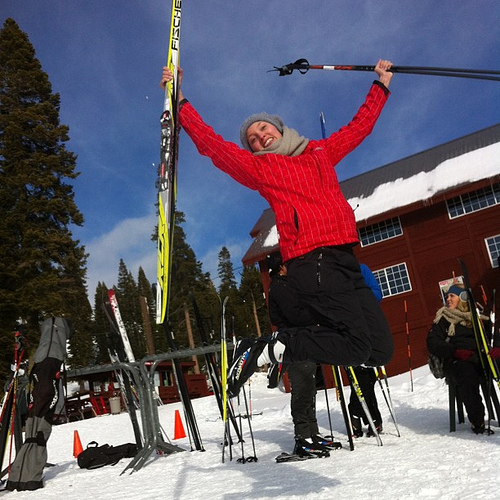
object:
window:
[371, 261, 414, 298]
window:
[356, 216, 404, 248]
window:
[446, 180, 500, 221]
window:
[483, 233, 500, 269]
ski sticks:
[265, 57, 500, 83]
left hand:
[374, 57, 394, 78]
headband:
[446, 283, 467, 297]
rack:
[49, 337, 249, 478]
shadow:
[174, 449, 341, 500]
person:
[160, 60, 396, 396]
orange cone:
[72, 430, 85, 457]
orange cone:
[173, 409, 186, 439]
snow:
[0, 368, 498, 498]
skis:
[156, 0, 181, 326]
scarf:
[432, 302, 472, 334]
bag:
[7, 315, 70, 491]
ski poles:
[218, 296, 258, 462]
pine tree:
[1, 12, 93, 358]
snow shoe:
[220, 334, 269, 398]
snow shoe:
[293, 438, 333, 458]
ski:
[0, 303, 88, 498]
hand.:
[159, 65, 187, 94]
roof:
[243, 125, 500, 268]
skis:
[4, 316, 65, 488]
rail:
[61, 340, 268, 382]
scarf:
[253, 125, 309, 165]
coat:
[176, 79, 390, 262]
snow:
[263, 136, 499, 249]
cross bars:
[367, 262, 414, 299]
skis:
[216, 294, 233, 463]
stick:
[264, 59, 498, 85]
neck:
[273, 144, 299, 158]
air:
[122, 38, 447, 352]